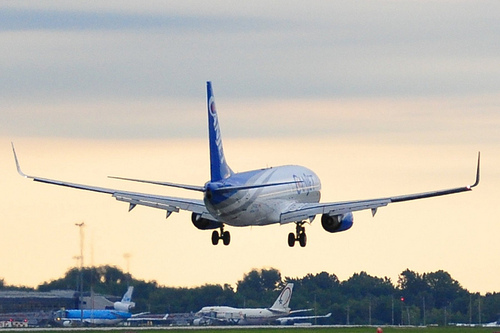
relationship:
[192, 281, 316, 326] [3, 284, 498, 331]
airplanes preparing to land at airport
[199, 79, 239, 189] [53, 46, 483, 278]
tail on plane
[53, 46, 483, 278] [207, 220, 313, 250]
plane has wheels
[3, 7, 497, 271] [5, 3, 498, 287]
clouds in sky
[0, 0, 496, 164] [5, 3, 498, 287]
clouds in sky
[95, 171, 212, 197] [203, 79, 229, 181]
wing on plane tail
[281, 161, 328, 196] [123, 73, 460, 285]
logo on plane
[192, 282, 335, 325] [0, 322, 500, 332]
airplanes on ground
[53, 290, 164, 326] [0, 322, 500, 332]
airplanes on ground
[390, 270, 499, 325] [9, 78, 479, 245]
trees behind planes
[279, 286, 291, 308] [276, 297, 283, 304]
circle and star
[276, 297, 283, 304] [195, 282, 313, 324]
star on plane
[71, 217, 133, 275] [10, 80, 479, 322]
towers behind planes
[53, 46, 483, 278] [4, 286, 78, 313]
plane in airport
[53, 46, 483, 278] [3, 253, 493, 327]
plane in airport